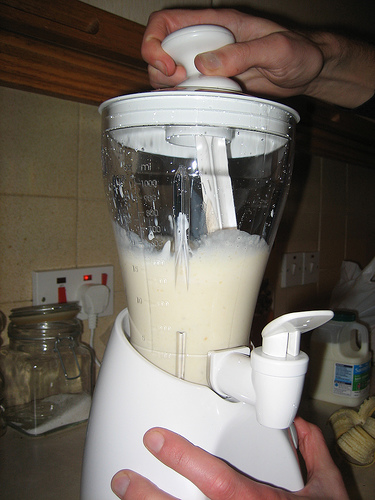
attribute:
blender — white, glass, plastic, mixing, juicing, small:
[95, 16, 293, 461]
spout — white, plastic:
[253, 306, 293, 424]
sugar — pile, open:
[5, 312, 80, 429]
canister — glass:
[2, 274, 92, 436]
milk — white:
[316, 381, 352, 400]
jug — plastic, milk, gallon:
[313, 297, 370, 400]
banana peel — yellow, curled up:
[333, 411, 365, 461]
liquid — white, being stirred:
[178, 286, 242, 312]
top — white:
[104, 48, 284, 132]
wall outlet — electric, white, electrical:
[25, 264, 114, 316]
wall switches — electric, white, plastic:
[276, 244, 328, 357]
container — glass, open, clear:
[9, 330, 70, 339]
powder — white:
[47, 402, 83, 415]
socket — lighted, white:
[76, 268, 111, 325]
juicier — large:
[126, 114, 271, 448]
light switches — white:
[282, 256, 320, 288]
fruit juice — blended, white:
[112, 263, 258, 347]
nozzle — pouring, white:
[229, 315, 320, 440]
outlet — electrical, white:
[287, 257, 309, 291]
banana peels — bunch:
[314, 373, 369, 473]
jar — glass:
[1, 253, 88, 378]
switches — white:
[290, 262, 324, 291]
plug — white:
[84, 293, 102, 306]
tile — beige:
[8, 153, 90, 195]